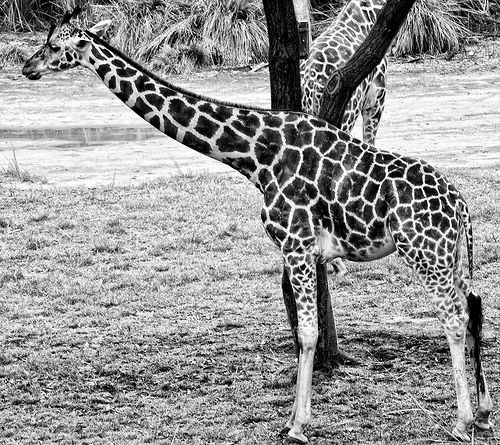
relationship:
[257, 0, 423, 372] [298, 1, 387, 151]
tree in middle of giraffe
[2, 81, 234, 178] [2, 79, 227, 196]
pond with moss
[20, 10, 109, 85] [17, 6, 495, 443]
head of giraffe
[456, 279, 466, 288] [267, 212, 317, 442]
patches on leg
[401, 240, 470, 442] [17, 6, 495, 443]
leg of giraffe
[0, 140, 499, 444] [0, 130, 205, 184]
grass growing from pond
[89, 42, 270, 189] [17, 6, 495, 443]
neck of giraffe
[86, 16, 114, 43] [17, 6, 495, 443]
ears of giraffe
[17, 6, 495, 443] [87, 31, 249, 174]
giraffe with neck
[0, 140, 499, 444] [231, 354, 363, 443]
grass below feet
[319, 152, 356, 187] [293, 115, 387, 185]
spots on giraffe's back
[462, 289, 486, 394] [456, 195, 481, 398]
hair on tail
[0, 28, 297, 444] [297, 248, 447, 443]
ground has grass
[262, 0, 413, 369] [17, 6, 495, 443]
tree in between giraffe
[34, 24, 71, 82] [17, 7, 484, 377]
eye of giraffe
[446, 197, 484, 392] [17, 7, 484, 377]
tail of giraffe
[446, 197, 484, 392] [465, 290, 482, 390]
tail with fringes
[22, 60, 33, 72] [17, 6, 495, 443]
nose of giraffe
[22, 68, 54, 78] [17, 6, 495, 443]
mouth of giraffe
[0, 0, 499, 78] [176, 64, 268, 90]
grass shrubs with dirt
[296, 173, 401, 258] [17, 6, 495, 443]
stomach of giraffe